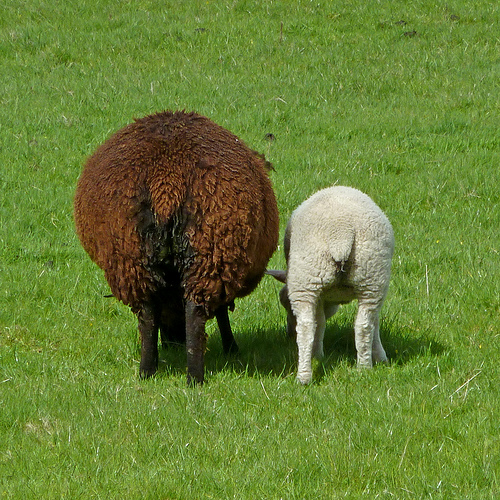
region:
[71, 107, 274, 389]
brown sheep is next to white sheep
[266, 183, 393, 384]
white sheep was next to brown sheep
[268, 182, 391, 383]
white sheep on top of grass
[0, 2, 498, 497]
green grass under white sheep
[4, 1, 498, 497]
green grass under brown sheep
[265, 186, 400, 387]
white sheep grazing on grass field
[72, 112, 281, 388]
brown sheep grazing on grass field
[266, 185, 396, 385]
white sheep is small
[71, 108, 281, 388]
brown sheep is large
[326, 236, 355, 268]
white tail on sheep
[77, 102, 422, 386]
the butts of two sheep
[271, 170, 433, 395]
a little white sheep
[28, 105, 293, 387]
a big brown sheep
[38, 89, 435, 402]
one big, one little sheep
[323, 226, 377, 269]
little white tail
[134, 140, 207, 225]
little brown tail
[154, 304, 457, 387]
shadow on ground from sheep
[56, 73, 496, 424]
two sheep eating grass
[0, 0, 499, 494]
a field of green grass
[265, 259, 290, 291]
a white pointed ear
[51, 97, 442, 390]
two sheep in a field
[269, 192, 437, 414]
a small white sheep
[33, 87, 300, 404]
a large brown sheep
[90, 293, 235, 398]
dark brown legs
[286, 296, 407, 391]
little white legs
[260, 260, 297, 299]
a white pointy ear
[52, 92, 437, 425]
two sheep standing together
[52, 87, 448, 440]
two sheep eating together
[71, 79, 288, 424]
Brown animal in field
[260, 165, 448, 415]
White animal in field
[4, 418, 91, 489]
Patch of green grass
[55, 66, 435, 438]
Two animals in field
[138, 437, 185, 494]
Patch of green grass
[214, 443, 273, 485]
Patch of green grass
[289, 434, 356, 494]
Patch of green grass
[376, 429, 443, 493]
Patch of green grass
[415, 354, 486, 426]
Patch of green grass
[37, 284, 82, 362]
Patch of green grass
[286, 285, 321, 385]
the back leg of a sheep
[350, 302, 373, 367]
the back leg of a sheep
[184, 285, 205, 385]
the back leg of a sheep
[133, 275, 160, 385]
the back leg of a sheep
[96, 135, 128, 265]
the wool on a sheep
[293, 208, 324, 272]
the wool on a sheep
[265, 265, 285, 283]
the ear of a sheep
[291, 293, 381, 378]
the back legs of a sheep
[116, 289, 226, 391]
the back legs of a sheep